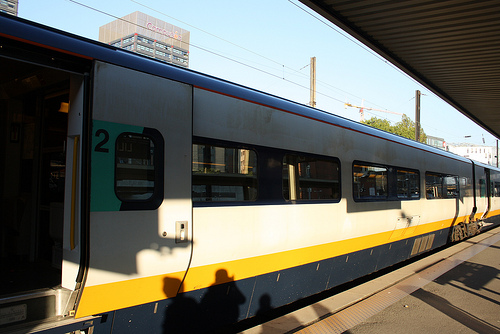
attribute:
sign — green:
[93, 120, 143, 210]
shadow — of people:
[162, 266, 274, 331]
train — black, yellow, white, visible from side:
[0, 13, 500, 333]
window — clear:
[115, 133, 155, 198]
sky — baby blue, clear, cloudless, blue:
[18, 0, 500, 167]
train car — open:
[0, 12, 477, 331]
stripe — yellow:
[74, 209, 499, 318]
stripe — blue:
[83, 213, 499, 331]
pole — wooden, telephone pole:
[309, 57, 318, 107]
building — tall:
[99, 11, 191, 68]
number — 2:
[94, 128, 111, 154]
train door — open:
[1, 38, 84, 333]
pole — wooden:
[415, 89, 422, 141]